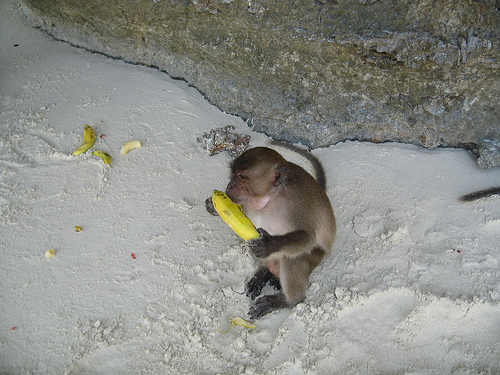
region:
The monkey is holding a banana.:
[209, 170, 264, 269]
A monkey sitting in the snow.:
[231, 162, 325, 309]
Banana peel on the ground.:
[54, 116, 144, 164]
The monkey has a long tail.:
[266, 100, 336, 176]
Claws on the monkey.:
[247, 277, 271, 319]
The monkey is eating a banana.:
[192, 157, 296, 236]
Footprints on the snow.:
[88, 251, 215, 351]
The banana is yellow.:
[226, 200, 256, 253]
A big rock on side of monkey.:
[219, 7, 421, 142]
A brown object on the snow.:
[196, 119, 258, 167]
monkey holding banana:
[207, 127, 347, 317]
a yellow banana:
[197, 182, 275, 264]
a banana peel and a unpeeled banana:
[70, 124, 152, 175]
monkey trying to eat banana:
[198, 129, 359, 327]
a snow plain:
[33, 288, 165, 373]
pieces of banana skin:
[207, 312, 266, 341]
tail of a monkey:
[262, 130, 349, 200]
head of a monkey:
[214, 136, 292, 206]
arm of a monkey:
[243, 227, 309, 264]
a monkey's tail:
[457, 172, 499, 213]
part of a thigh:
[279, 276, 291, 300]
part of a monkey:
[318, 217, 340, 253]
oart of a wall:
[405, 99, 435, 135]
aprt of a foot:
[255, 303, 315, 333]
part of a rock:
[361, 120, 378, 164]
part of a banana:
[235, 215, 248, 235]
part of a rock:
[373, 29, 381, 109]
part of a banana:
[260, 224, 278, 242]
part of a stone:
[379, 105, 395, 169]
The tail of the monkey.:
[273, 136, 335, 181]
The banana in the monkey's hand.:
[208, 192, 257, 240]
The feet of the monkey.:
[241, 269, 290, 314]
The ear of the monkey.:
[274, 159, 290, 191]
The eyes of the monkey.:
[226, 172, 248, 178]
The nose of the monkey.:
[226, 181, 236, 190]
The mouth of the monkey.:
[229, 193, 242, 203]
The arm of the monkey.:
[272, 224, 315, 251]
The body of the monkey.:
[243, 192, 335, 257]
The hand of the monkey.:
[253, 229, 272, 254]